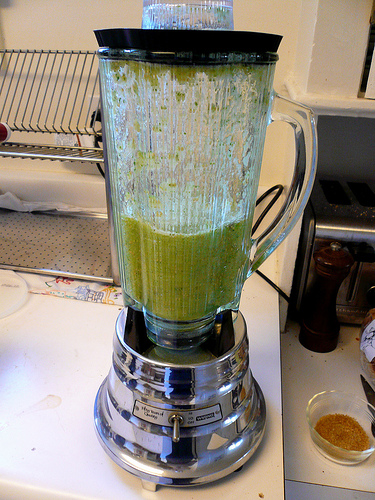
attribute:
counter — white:
[4, 263, 277, 497]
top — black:
[95, 1, 289, 58]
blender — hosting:
[93, 0, 319, 489]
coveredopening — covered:
[142, 1, 234, 28]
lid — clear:
[5, 272, 25, 307]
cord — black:
[242, 183, 302, 310]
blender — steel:
[45, 9, 336, 372]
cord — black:
[253, 268, 300, 314]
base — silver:
[94, 322, 270, 489]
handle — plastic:
[282, 119, 327, 254]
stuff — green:
[114, 209, 253, 318]